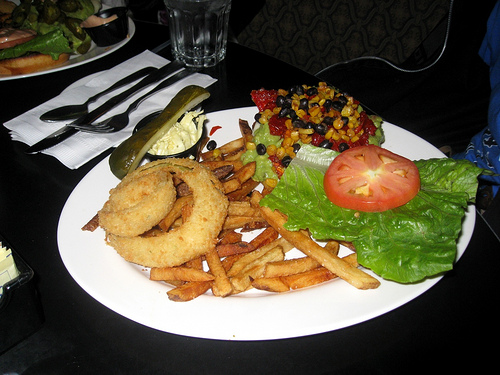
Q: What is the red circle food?
A: Tomato.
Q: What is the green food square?
A: Lettuce.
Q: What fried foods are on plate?
A: French fries, onion rings.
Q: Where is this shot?
A: Table.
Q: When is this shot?
A: Night time.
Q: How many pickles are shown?
A: 1.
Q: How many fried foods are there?
A: 2.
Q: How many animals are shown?
A: 0.